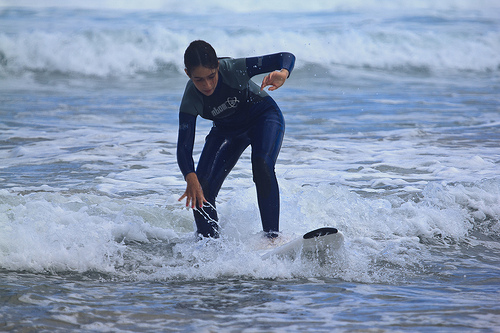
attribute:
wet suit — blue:
[170, 53, 296, 241]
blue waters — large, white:
[1, 1, 482, 330]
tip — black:
[295, 218, 354, 245]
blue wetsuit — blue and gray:
[168, 56, 300, 235]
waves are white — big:
[3, 32, 499, 82]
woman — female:
[160, 35, 300, 238]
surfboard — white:
[226, 226, 343, 266]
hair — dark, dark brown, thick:
[172, 39, 226, 73]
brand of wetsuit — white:
[206, 98, 249, 116]